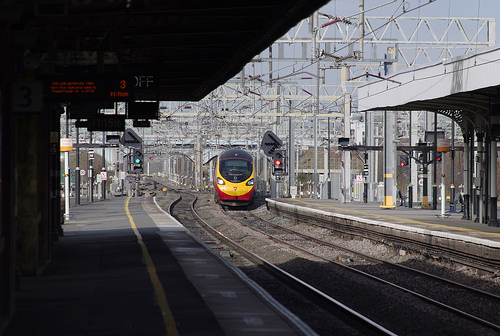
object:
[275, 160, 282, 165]
light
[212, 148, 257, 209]
train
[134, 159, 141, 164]
light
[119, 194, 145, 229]
line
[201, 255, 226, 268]
dirt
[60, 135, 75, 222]
post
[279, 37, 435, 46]
bars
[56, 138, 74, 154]
sign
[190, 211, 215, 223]
track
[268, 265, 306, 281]
tracks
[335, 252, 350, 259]
gravel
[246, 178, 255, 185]
headlights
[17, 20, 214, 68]
building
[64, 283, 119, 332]
shade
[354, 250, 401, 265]
rail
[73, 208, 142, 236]
lane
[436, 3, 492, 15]
sky